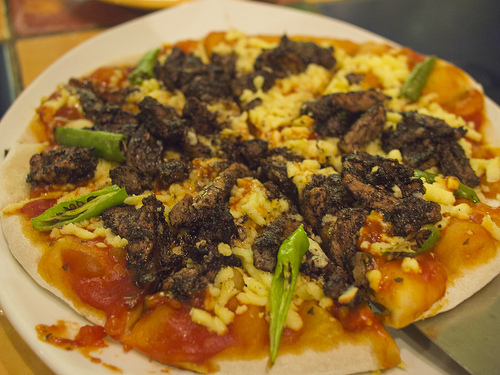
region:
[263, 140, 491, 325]
a slice of pizza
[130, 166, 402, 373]
a slice of pizza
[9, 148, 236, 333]
a slice of pizza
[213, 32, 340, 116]
a slice of pizza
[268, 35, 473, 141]
a slice of pizza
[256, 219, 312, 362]
green pepper topping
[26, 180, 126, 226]
green pepper topping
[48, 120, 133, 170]
green pepper topping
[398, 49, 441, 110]
green pepper topping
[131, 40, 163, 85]
green pepper topping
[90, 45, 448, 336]
pizza on a plate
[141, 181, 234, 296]
brown topping on pizza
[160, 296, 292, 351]
red sauce on pizza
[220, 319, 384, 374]
brown crust on pizza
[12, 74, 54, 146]
white plate beneath pizza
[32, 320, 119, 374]
sauce on the plate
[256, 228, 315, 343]
green peppers on pizza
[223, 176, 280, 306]
yellow stuff on pizza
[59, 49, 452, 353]
seven pieces of pizza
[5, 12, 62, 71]
table beneath the pizza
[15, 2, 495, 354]
taco pizza on table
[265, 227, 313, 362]
piece of green pepper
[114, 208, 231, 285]
brown grilled meat on taco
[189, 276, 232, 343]
yellow rice on tortilla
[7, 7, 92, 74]
orange and red tile of table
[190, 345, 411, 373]
side of tortilla shell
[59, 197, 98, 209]
seeds inside of a pepper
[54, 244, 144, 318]
red sauce on taco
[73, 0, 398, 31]
napkin underneath the food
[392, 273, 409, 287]
piece of an herb on taco pizza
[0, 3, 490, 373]
a flour burrito sliced in half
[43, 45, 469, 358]
fresh green peppers are on top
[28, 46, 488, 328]
a dark meat is abundant on top of the dish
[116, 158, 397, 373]
a slice of quesadilla with cheese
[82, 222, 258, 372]
a tomato salsa with cheese on the burrito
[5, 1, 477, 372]
the dish is on a tiled table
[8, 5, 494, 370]
the plate is white underneath the food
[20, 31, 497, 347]
a steak and cheese quesadilla ready to eat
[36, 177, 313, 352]
the seeds are in the green peppers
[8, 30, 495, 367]
a chicken, cheese, and salsa quesadilla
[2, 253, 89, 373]
White plate on table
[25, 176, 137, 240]
Green pepper with seeds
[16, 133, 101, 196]
Cooked and dark beef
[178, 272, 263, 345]
Yellow cheese scattered on tortilla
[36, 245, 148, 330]
Red tomato cooking sauce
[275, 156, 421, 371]
Dividing cut in tortilla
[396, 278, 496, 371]
Shiny and chrome surface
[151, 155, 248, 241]
Cooked brown-colored pork meat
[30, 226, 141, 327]
Orange taco flavoring sauce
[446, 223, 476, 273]
Small green food spice